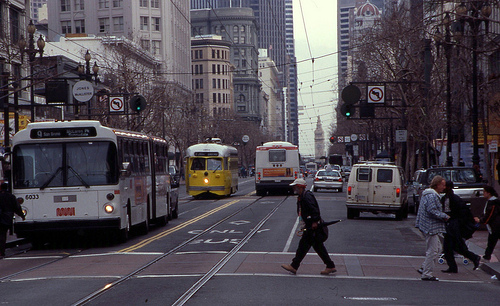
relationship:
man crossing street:
[282, 175, 342, 275] [9, 161, 498, 304]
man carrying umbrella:
[282, 175, 342, 275] [293, 213, 344, 237]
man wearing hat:
[282, 175, 342, 275] [287, 176, 309, 189]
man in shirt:
[415, 167, 453, 282] [415, 183, 449, 238]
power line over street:
[11, 54, 467, 102] [9, 161, 498, 304]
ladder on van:
[352, 158, 373, 216] [340, 156, 412, 219]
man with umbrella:
[282, 175, 342, 275] [293, 213, 344, 237]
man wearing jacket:
[282, 175, 342, 275] [294, 189, 325, 230]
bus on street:
[8, 118, 197, 257] [9, 161, 498, 304]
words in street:
[185, 214, 274, 255] [9, 161, 498, 304]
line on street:
[91, 166, 283, 275] [9, 161, 498, 304]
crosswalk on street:
[0, 250, 488, 287] [9, 161, 498, 304]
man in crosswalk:
[282, 175, 342, 275] [0, 250, 488, 287]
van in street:
[340, 156, 412, 219] [9, 161, 498, 304]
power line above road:
[24, 2, 477, 167] [9, 161, 498, 304]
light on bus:
[104, 201, 118, 215] [8, 118, 197, 257]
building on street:
[189, 31, 241, 170] [9, 161, 498, 304]